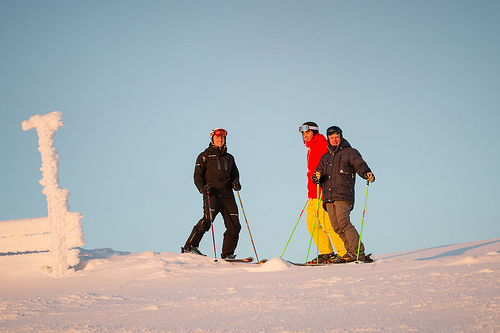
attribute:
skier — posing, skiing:
[294, 111, 340, 274]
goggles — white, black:
[294, 122, 319, 135]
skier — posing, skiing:
[179, 123, 262, 263]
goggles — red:
[204, 128, 233, 138]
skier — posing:
[314, 127, 381, 272]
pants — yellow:
[303, 188, 349, 270]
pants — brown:
[323, 198, 381, 269]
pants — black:
[191, 184, 251, 263]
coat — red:
[302, 135, 331, 202]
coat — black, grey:
[310, 144, 379, 209]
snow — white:
[1, 225, 499, 332]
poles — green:
[278, 187, 326, 275]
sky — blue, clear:
[3, 2, 498, 251]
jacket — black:
[196, 144, 242, 198]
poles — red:
[205, 185, 264, 273]